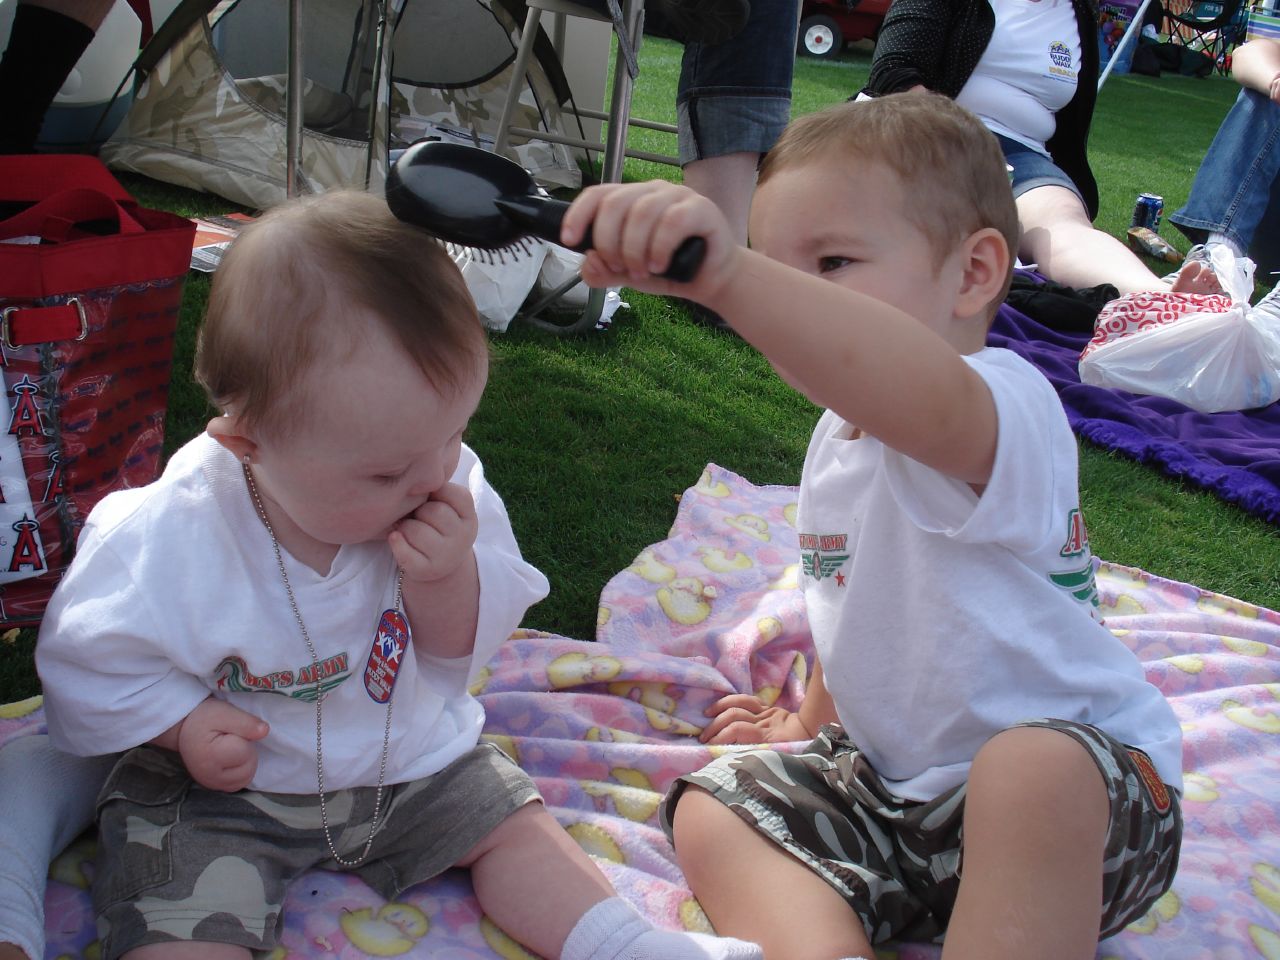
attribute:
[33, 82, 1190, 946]
kids — small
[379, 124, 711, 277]
brush — black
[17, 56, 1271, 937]
children — small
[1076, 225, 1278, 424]
bag — red, white, plastic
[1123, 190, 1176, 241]
can — blue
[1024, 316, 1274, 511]
blanket — blue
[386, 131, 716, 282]
brush — black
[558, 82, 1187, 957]
boy — small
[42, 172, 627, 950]
baby — sitting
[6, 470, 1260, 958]
blanket — pink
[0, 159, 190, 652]
bag — red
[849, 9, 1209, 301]
woman — fat, sitting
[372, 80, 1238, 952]
boy — small, little, sitting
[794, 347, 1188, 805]
shirt — white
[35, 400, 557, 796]
shirt — white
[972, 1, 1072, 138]
shirt — white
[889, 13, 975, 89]
sweater — black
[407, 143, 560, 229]
hair brush — black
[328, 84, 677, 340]
brush — hair brush 